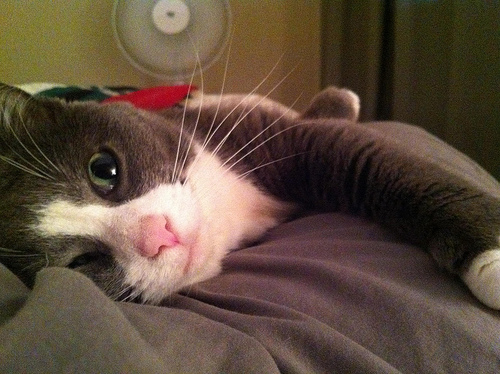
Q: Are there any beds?
A: Yes, there is a bed.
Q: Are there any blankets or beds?
A: Yes, there is a bed.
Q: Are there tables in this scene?
A: No, there are no tables.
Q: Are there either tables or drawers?
A: No, there are no tables or drawers.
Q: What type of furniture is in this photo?
A: The furniture is a bed.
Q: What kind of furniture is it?
A: The piece of furniture is a bed.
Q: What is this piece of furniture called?
A: That is a bed.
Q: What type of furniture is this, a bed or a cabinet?
A: That is a bed.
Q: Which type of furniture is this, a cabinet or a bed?
A: That is a bed.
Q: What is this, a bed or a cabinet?
A: This is a bed.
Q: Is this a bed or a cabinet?
A: This is a bed.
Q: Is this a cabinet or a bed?
A: This is a bed.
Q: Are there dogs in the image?
A: No, there are no dogs.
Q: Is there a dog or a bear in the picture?
A: No, there are no dogs or bears.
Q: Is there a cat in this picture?
A: Yes, there is a cat.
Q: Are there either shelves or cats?
A: Yes, there is a cat.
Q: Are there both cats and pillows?
A: Yes, there are both a cat and a pillow.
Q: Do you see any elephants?
A: No, there are no elephants.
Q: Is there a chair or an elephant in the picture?
A: No, there are no elephants or chairs.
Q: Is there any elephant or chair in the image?
A: No, there are no elephants or chairs.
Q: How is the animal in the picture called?
A: The animal is a cat.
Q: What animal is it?
A: The animal is a cat.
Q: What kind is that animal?
A: This is a cat.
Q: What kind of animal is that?
A: This is a cat.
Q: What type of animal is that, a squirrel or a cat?
A: This is a cat.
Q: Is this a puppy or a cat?
A: This is a cat.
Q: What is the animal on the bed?
A: The animal is a cat.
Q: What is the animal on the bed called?
A: The animal is a cat.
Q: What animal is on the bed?
A: The animal is a cat.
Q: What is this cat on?
A: The cat is on the bed.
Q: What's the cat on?
A: The cat is on the bed.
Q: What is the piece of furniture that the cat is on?
A: The piece of furniture is a bed.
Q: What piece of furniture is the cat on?
A: The cat is on the bed.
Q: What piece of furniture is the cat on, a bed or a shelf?
A: The cat is on a bed.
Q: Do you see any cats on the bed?
A: Yes, there is a cat on the bed.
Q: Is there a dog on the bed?
A: No, there is a cat on the bed.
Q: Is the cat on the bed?
A: Yes, the cat is on the bed.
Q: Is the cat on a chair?
A: No, the cat is on the bed.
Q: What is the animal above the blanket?
A: The animal is a cat.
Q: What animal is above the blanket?
A: The animal is a cat.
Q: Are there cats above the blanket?
A: Yes, there is a cat above the blanket.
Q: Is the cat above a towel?
A: No, the cat is above the blanket.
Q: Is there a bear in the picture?
A: No, there are no bears.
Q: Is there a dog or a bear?
A: No, there are no bears or dogs.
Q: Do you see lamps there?
A: No, there are no lamps.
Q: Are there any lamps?
A: No, there are no lamps.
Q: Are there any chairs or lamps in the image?
A: No, there are no lamps or chairs.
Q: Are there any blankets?
A: Yes, there is a blanket.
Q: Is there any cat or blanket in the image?
A: Yes, there is a blanket.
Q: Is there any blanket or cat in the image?
A: Yes, there is a blanket.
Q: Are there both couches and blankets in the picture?
A: No, there is a blanket but no couches.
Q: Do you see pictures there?
A: No, there are no pictures.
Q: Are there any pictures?
A: No, there are no pictures.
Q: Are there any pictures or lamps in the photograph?
A: No, there are no pictures or lamps.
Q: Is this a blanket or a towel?
A: This is a blanket.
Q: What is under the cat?
A: The blanket is under the cat.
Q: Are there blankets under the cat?
A: Yes, there is a blanket under the cat.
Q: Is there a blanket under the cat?
A: Yes, there is a blanket under the cat.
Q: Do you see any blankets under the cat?
A: Yes, there is a blanket under the cat.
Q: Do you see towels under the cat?
A: No, there is a blanket under the cat.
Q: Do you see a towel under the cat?
A: No, there is a blanket under the cat.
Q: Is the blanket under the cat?
A: Yes, the blanket is under the cat.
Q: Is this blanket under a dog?
A: No, the blanket is under the cat.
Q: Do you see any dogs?
A: No, there are no dogs.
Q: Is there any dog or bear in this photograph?
A: No, there are no dogs or bears.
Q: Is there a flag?
A: No, there are no flags.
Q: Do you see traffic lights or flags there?
A: No, there are no flags or traffic lights.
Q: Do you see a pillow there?
A: Yes, there is a pillow.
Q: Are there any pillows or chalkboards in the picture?
A: Yes, there is a pillow.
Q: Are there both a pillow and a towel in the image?
A: No, there is a pillow but no towels.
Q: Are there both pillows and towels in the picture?
A: No, there is a pillow but no towels.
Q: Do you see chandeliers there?
A: No, there are no chandeliers.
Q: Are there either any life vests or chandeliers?
A: No, there are no chandeliers or life vests.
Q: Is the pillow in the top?
A: Yes, the pillow is in the top of the image.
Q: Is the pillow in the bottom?
A: No, the pillow is in the top of the image.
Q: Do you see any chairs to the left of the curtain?
A: No, there is a pillow to the left of the curtain.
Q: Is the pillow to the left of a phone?
A: No, the pillow is to the left of the curtain.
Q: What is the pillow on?
A: The pillow is on the bed.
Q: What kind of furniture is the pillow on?
A: The pillow is on the bed.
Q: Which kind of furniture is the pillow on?
A: The pillow is on the bed.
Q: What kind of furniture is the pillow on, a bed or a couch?
A: The pillow is on a bed.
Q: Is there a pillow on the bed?
A: Yes, there is a pillow on the bed.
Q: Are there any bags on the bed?
A: No, there is a pillow on the bed.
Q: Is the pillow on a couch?
A: No, the pillow is on the bed.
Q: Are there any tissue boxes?
A: No, there are no tissue boxes.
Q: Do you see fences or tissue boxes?
A: No, there are no tissue boxes or fences.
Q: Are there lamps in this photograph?
A: No, there are no lamps.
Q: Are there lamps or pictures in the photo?
A: No, there are no lamps or pictures.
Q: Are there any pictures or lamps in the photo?
A: No, there are no lamps or pictures.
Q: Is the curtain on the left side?
A: No, the curtain is on the right of the image.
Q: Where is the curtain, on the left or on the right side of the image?
A: The curtain is on the right of the image.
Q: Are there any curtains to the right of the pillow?
A: Yes, there is a curtain to the right of the pillow.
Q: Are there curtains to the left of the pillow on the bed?
A: No, the curtain is to the right of the pillow.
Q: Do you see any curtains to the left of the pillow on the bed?
A: No, the curtain is to the right of the pillow.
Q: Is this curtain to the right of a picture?
A: No, the curtain is to the right of a pillow.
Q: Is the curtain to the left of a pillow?
A: No, the curtain is to the right of a pillow.